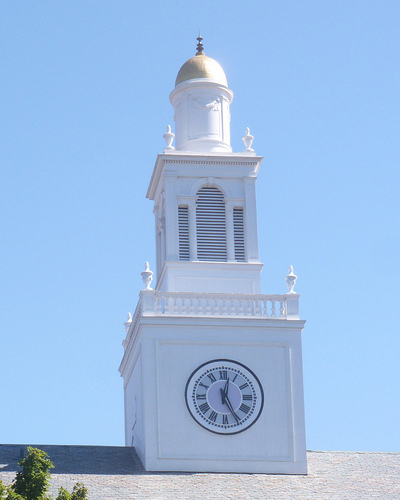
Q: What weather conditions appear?
A: It is clear.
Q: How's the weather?
A: It is clear.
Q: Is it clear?
A: Yes, it is clear.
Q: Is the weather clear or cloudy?
A: It is clear.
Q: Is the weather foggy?
A: No, it is clear.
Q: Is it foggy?
A: No, it is clear.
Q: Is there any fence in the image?
A: No, there are no fences.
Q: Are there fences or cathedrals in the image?
A: No, there are no fences or cathedrals.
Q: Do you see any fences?
A: No, there are no fences.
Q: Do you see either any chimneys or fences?
A: No, there are no fences or chimneys.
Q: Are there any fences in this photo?
A: No, there are no fences.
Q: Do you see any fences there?
A: No, there are no fences.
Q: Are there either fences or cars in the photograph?
A: No, there are no fences or cars.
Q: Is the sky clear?
A: Yes, the sky is clear.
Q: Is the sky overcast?
A: No, the sky is clear.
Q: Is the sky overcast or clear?
A: The sky is clear.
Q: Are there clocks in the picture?
A: Yes, there is a clock.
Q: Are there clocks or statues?
A: Yes, there is a clock.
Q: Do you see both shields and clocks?
A: No, there is a clock but no shields.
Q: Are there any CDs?
A: No, there are no cds.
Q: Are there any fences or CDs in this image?
A: No, there are no CDs or fences.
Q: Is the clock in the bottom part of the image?
A: Yes, the clock is in the bottom of the image.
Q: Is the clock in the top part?
A: No, the clock is in the bottom of the image.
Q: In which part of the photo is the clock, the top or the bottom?
A: The clock is in the bottom of the image.